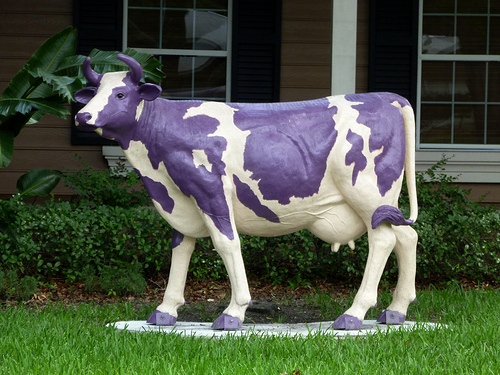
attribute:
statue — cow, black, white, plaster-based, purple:
[64, 44, 435, 343]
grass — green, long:
[6, 295, 495, 367]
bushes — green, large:
[11, 15, 82, 115]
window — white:
[119, 3, 497, 88]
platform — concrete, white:
[106, 312, 446, 339]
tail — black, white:
[398, 94, 424, 227]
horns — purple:
[77, 49, 148, 81]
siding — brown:
[80, 4, 179, 54]